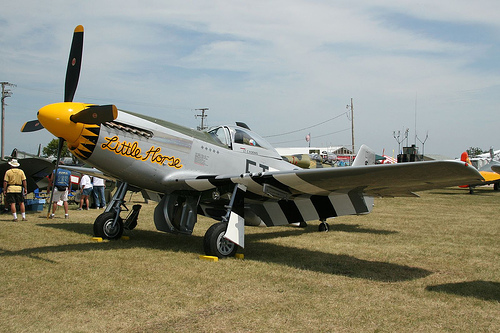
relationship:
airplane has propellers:
[10, 20, 495, 271] [10, 18, 120, 149]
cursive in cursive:
[101, 136, 184, 170] [95, 133, 186, 169]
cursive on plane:
[101, 136, 184, 170] [10, 20, 495, 271]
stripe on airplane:
[185, 173, 375, 227] [10, 20, 495, 271]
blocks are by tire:
[85, 232, 251, 271] [86, 209, 246, 258]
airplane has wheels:
[10, 20, 495, 271] [82, 193, 244, 267]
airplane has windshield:
[10, 20, 495, 271] [209, 123, 276, 160]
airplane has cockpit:
[10, 20, 495, 271] [197, 120, 291, 162]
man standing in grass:
[2, 155, 39, 228] [1, 147, 500, 326]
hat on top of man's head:
[6, 156, 24, 170] [3, 155, 23, 173]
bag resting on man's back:
[54, 179, 72, 195] [45, 168, 76, 195]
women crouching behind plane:
[74, 166, 94, 206] [10, 20, 495, 271]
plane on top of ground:
[10, 20, 495, 271] [0, 147, 500, 331]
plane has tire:
[10, 20, 495, 271] [203, 222, 239, 259]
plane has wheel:
[10, 20, 495, 271] [81, 208, 135, 246]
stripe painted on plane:
[188, 171, 372, 222] [10, 20, 495, 271]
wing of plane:
[161, 140, 498, 224] [10, 20, 495, 271]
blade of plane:
[50, 20, 85, 112] [10, 20, 495, 271]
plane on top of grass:
[10, 20, 495, 271] [1, 147, 500, 326]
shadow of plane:
[0, 217, 441, 291] [10, 20, 495, 271]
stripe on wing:
[185, 173, 375, 227] [161, 140, 498, 224]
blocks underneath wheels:
[85, 232, 251, 271] [82, 193, 244, 267]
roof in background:
[267, 141, 364, 159] [4, 0, 500, 203]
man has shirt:
[2, 155, 39, 228] [2, 167, 27, 195]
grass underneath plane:
[1, 147, 500, 326] [10, 20, 495, 271]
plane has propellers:
[10, 20, 495, 271] [10, 18, 120, 149]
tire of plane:
[203, 222, 239, 259] [10, 20, 495, 271]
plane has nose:
[10, 20, 495, 271] [23, 96, 105, 147]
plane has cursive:
[10, 20, 495, 271] [101, 136, 184, 170]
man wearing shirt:
[2, 155, 39, 228] [2, 167, 27, 195]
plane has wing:
[10, 20, 495, 271] [161, 140, 498, 224]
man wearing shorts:
[2, 155, 39, 228] [2, 187, 28, 207]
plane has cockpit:
[10, 20, 495, 271] [197, 120, 291, 162]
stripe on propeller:
[185, 173, 375, 227] [14, 17, 122, 142]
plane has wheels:
[10, 20, 495, 271] [82, 193, 244, 267]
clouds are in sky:
[137, 1, 492, 75] [2, 0, 499, 172]